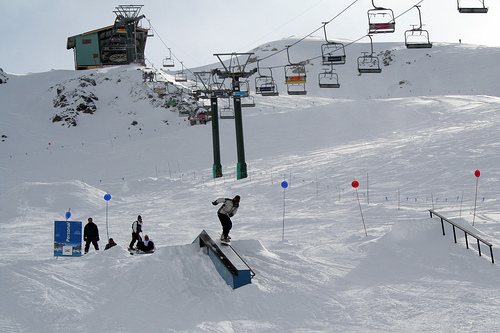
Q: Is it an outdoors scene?
A: Yes, it is outdoors.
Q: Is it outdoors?
A: Yes, it is outdoors.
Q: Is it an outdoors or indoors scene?
A: It is outdoors.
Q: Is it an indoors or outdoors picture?
A: It is outdoors.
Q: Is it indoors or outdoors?
A: It is outdoors.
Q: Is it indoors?
A: No, it is outdoors.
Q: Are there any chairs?
A: Yes, there is a chair.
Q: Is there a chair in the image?
A: Yes, there is a chair.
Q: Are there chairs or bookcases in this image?
A: Yes, there is a chair.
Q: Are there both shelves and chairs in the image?
A: No, there is a chair but no shelves.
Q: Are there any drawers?
A: No, there are no drawers.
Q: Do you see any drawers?
A: No, there are no drawers.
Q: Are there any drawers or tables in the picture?
A: No, there are no drawers or tables.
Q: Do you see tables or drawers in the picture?
A: No, there are no drawers or tables.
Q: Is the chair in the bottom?
A: No, the chair is in the top of the image.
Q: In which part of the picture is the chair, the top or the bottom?
A: The chair is in the top of the image.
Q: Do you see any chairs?
A: Yes, there is a chair.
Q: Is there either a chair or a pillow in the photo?
A: Yes, there is a chair.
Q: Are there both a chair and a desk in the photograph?
A: No, there is a chair but no desks.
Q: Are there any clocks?
A: No, there are no clocks.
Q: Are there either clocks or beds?
A: No, there are no clocks or beds.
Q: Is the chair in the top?
A: Yes, the chair is in the top of the image.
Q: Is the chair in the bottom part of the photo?
A: No, the chair is in the top of the image.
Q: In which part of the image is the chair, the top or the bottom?
A: The chair is in the top of the image.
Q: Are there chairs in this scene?
A: Yes, there is a chair.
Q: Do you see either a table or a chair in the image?
A: Yes, there is a chair.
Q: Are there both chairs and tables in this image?
A: No, there is a chair but no tables.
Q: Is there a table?
A: No, there are no tables.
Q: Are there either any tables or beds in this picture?
A: No, there are no tables or beds.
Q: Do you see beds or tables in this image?
A: No, there are no tables or beds.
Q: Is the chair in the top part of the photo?
A: Yes, the chair is in the top of the image.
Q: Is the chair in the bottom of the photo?
A: No, the chair is in the top of the image.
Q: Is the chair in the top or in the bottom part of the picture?
A: The chair is in the top of the image.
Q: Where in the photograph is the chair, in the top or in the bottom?
A: The chair is in the top of the image.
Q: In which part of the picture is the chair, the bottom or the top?
A: The chair is in the top of the image.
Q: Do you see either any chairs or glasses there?
A: Yes, there is a chair.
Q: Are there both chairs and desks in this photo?
A: No, there is a chair but no desks.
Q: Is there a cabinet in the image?
A: No, there are no cabinets.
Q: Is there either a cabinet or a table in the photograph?
A: No, there are no cabinets or tables.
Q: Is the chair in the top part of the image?
A: Yes, the chair is in the top of the image.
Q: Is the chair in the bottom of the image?
A: No, the chair is in the top of the image.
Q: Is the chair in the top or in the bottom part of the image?
A: The chair is in the top of the image.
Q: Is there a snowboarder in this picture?
A: Yes, there is a snowboarder.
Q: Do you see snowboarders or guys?
A: Yes, there is a snowboarder.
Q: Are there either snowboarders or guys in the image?
A: Yes, there is a snowboarder.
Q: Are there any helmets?
A: No, there are no helmets.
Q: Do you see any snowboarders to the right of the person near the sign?
A: Yes, there is a snowboarder to the right of the person.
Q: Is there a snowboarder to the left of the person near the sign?
A: No, the snowboarder is to the right of the person.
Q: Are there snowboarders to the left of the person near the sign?
A: No, the snowboarder is to the right of the person.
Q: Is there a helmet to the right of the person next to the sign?
A: No, there is a snowboarder to the right of the person.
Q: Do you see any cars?
A: No, there are no cars.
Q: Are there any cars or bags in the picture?
A: No, there are no cars or bags.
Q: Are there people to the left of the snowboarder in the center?
A: Yes, there are people to the left of the snowboarder.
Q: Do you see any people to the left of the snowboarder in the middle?
A: Yes, there are people to the left of the snowboarder.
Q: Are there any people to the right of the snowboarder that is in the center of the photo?
A: No, the people are to the left of the snowboarder.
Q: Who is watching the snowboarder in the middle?
A: The people are watching the snowboarder.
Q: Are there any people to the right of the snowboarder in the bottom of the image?
A: No, the people are to the left of the snowboarder.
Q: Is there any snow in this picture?
A: Yes, there is snow.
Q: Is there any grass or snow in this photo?
A: Yes, there is snow.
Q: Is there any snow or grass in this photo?
A: Yes, there is snow.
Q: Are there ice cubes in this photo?
A: No, there are no ice cubes.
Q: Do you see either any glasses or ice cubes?
A: No, there are no ice cubes or glasses.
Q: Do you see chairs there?
A: Yes, there is a chair.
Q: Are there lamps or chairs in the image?
A: Yes, there is a chair.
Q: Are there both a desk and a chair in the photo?
A: No, there is a chair but no desks.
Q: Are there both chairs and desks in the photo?
A: No, there is a chair but no desks.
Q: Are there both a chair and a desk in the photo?
A: No, there is a chair but no desks.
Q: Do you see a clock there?
A: No, there are no clocks.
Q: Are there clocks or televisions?
A: No, there are no clocks or televisions.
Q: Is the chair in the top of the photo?
A: Yes, the chair is in the top of the image.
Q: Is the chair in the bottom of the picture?
A: No, the chair is in the top of the image.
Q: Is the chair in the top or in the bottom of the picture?
A: The chair is in the top of the image.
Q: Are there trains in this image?
A: No, there are no trains.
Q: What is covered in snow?
A: The hill side is covered in snow.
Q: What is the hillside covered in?
A: The hillside is covered in snow.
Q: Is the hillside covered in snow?
A: Yes, the hillside is covered in snow.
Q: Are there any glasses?
A: No, there are no glasses.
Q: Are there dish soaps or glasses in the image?
A: No, there are no glasses or dish soaps.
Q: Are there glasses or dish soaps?
A: No, there are no glasses or dish soaps.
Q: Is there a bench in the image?
A: No, there are no benches.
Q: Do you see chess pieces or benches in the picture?
A: No, there are no benches or chess pieces.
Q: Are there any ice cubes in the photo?
A: No, there are no ice cubes.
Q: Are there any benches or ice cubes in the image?
A: No, there are no ice cubes or benches.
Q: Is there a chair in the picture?
A: Yes, there is a chair.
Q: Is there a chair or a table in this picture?
A: Yes, there is a chair.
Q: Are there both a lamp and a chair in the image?
A: No, there is a chair but no lamps.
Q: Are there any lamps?
A: No, there are no lamps.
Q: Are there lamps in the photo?
A: No, there are no lamps.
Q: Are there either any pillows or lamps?
A: No, there are no lamps or pillows.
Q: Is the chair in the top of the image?
A: Yes, the chair is in the top of the image.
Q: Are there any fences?
A: Yes, there is a fence.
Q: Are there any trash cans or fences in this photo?
A: Yes, there is a fence.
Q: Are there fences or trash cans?
A: Yes, there is a fence.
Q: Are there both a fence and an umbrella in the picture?
A: No, there is a fence but no umbrellas.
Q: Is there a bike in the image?
A: No, there are no bikes.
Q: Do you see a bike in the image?
A: No, there are no bikes.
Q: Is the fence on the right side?
A: Yes, the fence is on the right of the image.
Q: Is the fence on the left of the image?
A: No, the fence is on the right of the image.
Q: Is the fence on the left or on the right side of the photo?
A: The fence is on the right of the image.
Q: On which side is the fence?
A: The fence is on the right of the image.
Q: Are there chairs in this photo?
A: Yes, there is a chair.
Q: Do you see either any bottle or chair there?
A: Yes, there is a chair.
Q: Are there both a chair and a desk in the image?
A: No, there is a chair but no desks.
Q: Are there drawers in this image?
A: No, there are no drawers.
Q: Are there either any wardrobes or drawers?
A: No, there are no drawers or wardrobes.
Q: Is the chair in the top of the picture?
A: Yes, the chair is in the top of the image.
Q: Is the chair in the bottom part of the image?
A: No, the chair is in the top of the image.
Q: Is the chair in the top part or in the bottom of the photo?
A: The chair is in the top of the image.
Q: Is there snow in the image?
A: Yes, there is snow.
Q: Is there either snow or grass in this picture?
A: Yes, there is snow.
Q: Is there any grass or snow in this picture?
A: Yes, there is snow.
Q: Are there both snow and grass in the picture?
A: No, there is snow but no grass.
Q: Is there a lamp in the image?
A: No, there are no lamps.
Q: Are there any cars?
A: No, there are no cars.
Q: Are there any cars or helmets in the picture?
A: No, there are no cars or helmets.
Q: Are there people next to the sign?
A: Yes, there is a person next to the sign.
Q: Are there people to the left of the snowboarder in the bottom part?
A: Yes, there is a person to the left of the snowboarder.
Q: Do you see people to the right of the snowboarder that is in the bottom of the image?
A: No, the person is to the left of the snowboarder.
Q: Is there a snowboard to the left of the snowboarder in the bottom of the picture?
A: No, there is a person to the left of the snowboarder.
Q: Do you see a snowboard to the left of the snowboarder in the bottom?
A: No, there is a person to the left of the snowboarder.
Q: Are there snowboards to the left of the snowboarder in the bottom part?
A: No, there is a person to the left of the snowboarder.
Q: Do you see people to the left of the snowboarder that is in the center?
A: Yes, there is a person to the left of the snowboarder.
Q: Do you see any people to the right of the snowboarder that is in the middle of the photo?
A: No, the person is to the left of the snowboarder.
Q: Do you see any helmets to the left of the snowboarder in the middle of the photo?
A: No, there is a person to the left of the snowboarder.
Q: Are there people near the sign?
A: Yes, there is a person near the sign.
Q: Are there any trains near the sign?
A: No, there is a person near the sign.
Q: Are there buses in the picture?
A: No, there are no buses.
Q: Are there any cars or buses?
A: No, there are no buses or cars.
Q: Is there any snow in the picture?
A: Yes, there is snow.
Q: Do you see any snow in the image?
A: Yes, there is snow.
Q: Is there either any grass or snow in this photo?
A: Yes, there is snow.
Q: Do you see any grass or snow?
A: Yes, there is snow.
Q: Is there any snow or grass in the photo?
A: Yes, there is snow.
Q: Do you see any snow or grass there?
A: Yes, there is snow.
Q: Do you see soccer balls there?
A: No, there are no soccer balls.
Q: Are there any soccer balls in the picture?
A: No, there are no soccer balls.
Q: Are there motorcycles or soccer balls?
A: No, there are no soccer balls or motorcycles.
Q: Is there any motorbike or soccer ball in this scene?
A: No, there are no soccer balls or motorcycles.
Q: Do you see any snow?
A: Yes, there is snow.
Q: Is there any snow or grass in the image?
A: Yes, there is snow.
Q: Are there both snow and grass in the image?
A: No, there is snow but no grass.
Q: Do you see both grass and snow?
A: No, there is snow but no grass.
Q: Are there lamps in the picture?
A: No, there are no lamps.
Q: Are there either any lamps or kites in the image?
A: No, there are no lamps or kites.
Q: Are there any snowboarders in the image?
A: Yes, there is a snowboarder.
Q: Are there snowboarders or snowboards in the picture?
A: Yes, there is a snowboarder.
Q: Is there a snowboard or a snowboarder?
A: Yes, there is a snowboarder.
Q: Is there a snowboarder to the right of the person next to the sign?
A: Yes, there is a snowboarder to the right of the person.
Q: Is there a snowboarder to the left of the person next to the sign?
A: No, the snowboarder is to the right of the person.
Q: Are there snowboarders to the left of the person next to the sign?
A: No, the snowboarder is to the right of the person.